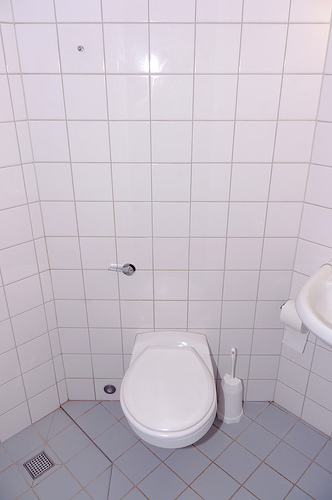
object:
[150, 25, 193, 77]
tile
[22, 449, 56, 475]
drain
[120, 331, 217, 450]
toilet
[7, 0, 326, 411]
wall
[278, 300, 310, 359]
tp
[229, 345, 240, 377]
brush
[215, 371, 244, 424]
holder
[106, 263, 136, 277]
handle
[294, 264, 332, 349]
sink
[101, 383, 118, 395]
pipe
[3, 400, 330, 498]
floor